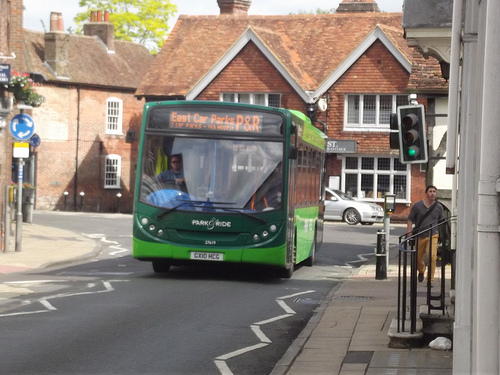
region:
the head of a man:
[423, 182, 440, 199]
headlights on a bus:
[250, 218, 281, 244]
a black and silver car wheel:
[340, 205, 362, 225]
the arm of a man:
[403, 201, 418, 243]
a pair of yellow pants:
[412, 231, 439, 291]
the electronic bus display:
[166, 105, 267, 139]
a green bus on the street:
[120, 97, 330, 282]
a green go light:
[402, 142, 419, 159]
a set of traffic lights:
[395, 101, 429, 167]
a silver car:
[318, 183, 385, 228]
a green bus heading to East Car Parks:
[380, 91, 444, 175]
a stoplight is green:
[380, 96, 450, 175]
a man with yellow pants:
[400, 182, 456, 284]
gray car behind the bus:
[327, 178, 388, 232]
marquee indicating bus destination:
[162, 100, 277, 139]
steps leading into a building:
[391, 228, 459, 349]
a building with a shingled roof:
[157, 8, 374, 98]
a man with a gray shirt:
[403, 177, 454, 233]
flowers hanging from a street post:
[7, 69, 50, 111]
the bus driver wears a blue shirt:
[151, 145, 199, 196]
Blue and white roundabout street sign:
[6, 108, 42, 150]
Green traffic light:
[389, 98, 434, 170]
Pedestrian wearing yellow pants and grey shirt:
[403, 180, 450, 283]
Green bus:
[125, 99, 307, 270]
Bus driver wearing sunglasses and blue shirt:
[148, 151, 193, 208]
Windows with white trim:
[342, 87, 393, 132]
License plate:
[186, 249, 228, 261]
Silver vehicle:
[328, 186, 388, 228]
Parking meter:
[379, 193, 394, 267]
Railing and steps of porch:
[391, 224, 477, 362]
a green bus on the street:
[133, 96, 325, 276]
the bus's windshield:
[138, 127, 281, 219]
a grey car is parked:
[317, 175, 381, 237]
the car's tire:
[340, 205, 357, 229]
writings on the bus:
[168, 107, 258, 142]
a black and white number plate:
[188, 245, 225, 264]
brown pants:
[404, 230, 439, 291]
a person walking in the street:
[401, 185, 446, 292]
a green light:
[405, 145, 420, 158]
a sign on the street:
[7, 107, 42, 154]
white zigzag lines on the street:
[207, 288, 324, 369]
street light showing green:
[390, 93, 431, 168]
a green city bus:
[130, 94, 336, 279]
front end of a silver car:
[318, 179, 387, 229]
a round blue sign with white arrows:
[7, 108, 45, 140]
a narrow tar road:
[18, 215, 350, 368]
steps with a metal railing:
[391, 212, 453, 347]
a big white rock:
[423, 327, 451, 352]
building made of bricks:
[139, 41, 436, 223]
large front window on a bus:
[130, 109, 297, 221]